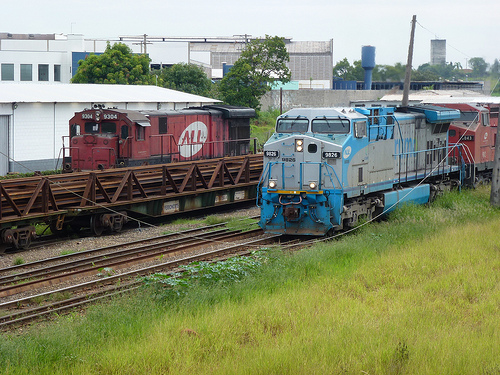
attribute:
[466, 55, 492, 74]
tree — far, distant, away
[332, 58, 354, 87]
tree — far off, distant, away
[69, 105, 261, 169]
engine — red, black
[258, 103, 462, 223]
engine — blue, grey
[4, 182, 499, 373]
grass — green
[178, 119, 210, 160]
logo — white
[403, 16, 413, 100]
pole — wooden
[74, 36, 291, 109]
trees — clustered, green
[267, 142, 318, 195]
headlights — white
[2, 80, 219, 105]
roof — white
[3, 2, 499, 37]
sky — white, cloudy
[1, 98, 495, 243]
wire — sagging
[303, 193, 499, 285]
slope — slight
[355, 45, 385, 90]
water tower — large